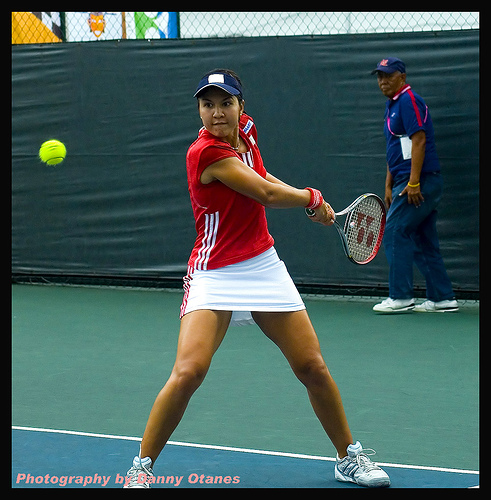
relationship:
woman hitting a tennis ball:
[177, 67, 264, 172] [38, 139, 68, 166]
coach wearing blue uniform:
[370, 56, 459, 314] [381, 102, 430, 174]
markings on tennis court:
[11, 422, 478, 487] [10, 277, 479, 486]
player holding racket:
[117, 68, 391, 487] [304, 193, 387, 265]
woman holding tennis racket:
[122, 69, 389, 488] [319, 189, 386, 267]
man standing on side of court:
[369, 56, 458, 313] [11, 12, 480, 489]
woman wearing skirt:
[122, 69, 389, 488] [179, 238, 303, 320]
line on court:
[10, 425, 479, 474] [26, 284, 479, 470]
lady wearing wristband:
[121, 66, 391, 497] [306, 185, 322, 208]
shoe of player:
[120, 445, 150, 486] [117, 68, 391, 487]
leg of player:
[244, 289, 401, 455] [117, 68, 391, 487]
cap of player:
[192, 72, 238, 100] [117, 68, 391, 487]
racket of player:
[329, 187, 391, 268] [117, 68, 391, 487]